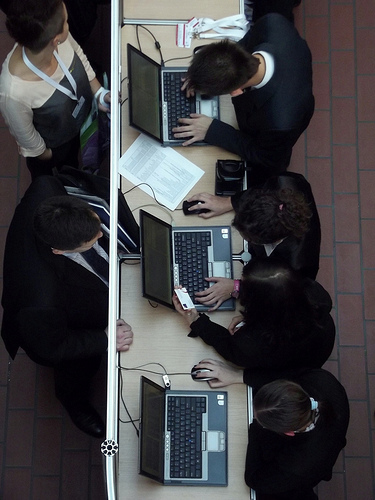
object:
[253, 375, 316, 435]
hair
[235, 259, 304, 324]
hair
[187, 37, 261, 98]
hair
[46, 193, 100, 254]
hair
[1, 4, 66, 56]
hair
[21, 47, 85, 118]
necklace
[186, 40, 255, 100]
head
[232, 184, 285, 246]
head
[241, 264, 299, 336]
head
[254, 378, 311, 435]
head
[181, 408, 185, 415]
buttons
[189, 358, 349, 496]
man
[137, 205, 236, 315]
laptop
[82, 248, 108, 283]
necktie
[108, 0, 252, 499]
table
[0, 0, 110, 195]
people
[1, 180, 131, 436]
man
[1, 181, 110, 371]
suit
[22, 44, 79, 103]
band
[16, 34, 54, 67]
neck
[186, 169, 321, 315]
person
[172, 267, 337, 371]
person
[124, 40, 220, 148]
laptop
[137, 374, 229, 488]
laptop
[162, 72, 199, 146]
keyboard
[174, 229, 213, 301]
keyboard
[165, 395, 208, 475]
keyboard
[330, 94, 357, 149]
brick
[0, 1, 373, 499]
picture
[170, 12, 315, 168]
man